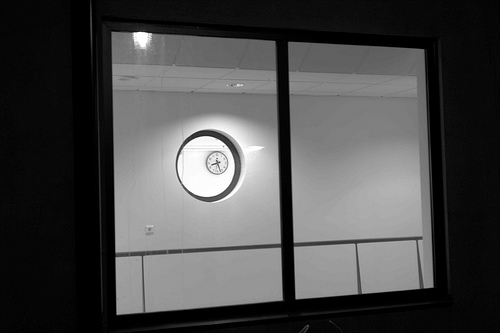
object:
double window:
[104, 32, 434, 315]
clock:
[175, 129, 246, 203]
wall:
[313, 117, 407, 222]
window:
[109, 26, 436, 318]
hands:
[217, 164, 222, 173]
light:
[132, 32, 153, 50]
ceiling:
[153, 36, 424, 60]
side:
[424, 37, 462, 301]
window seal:
[415, 37, 442, 57]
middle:
[272, 43, 298, 301]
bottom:
[0, 313, 500, 331]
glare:
[132, 31, 153, 49]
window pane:
[110, 31, 431, 314]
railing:
[115, 235, 432, 315]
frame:
[88, 1, 454, 333]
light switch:
[144, 225, 154, 233]